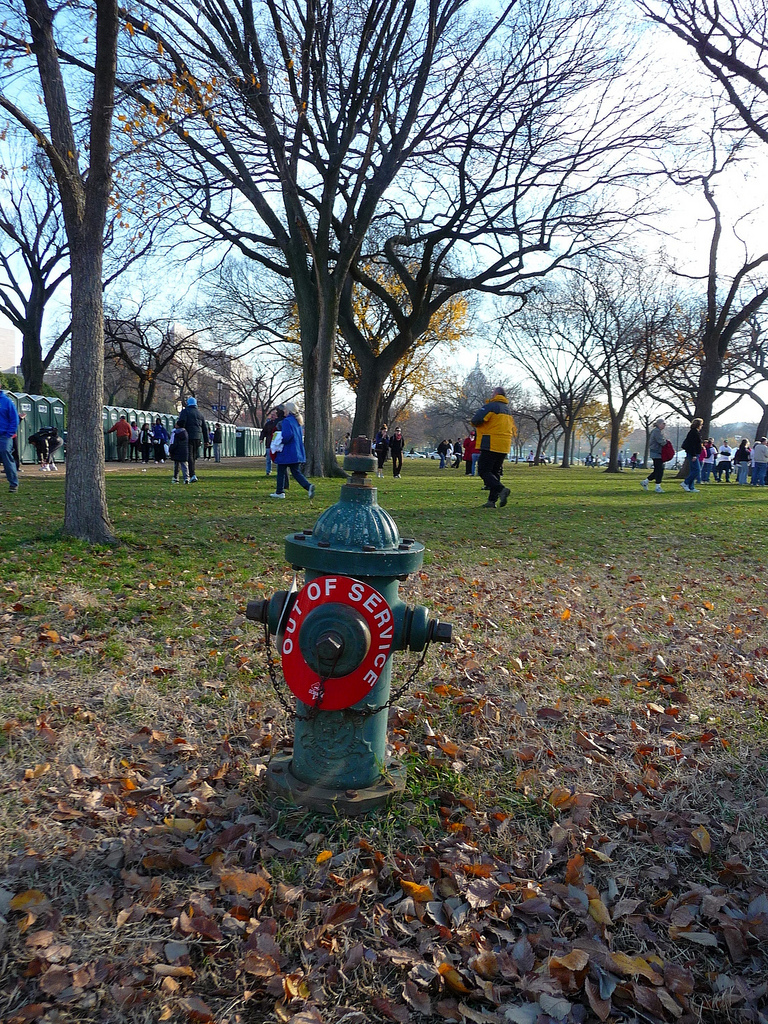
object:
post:
[292, 575, 400, 791]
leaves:
[545, 941, 595, 982]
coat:
[273, 415, 308, 465]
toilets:
[107, 404, 121, 460]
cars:
[406, 451, 427, 458]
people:
[0, 384, 23, 509]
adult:
[178, 395, 212, 484]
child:
[168, 417, 195, 488]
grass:
[378, 463, 768, 564]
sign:
[280, 576, 393, 711]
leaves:
[35, 947, 97, 1006]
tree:
[339, 229, 467, 472]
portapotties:
[17, 397, 37, 464]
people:
[526, 448, 536, 468]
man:
[467, 381, 521, 514]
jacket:
[468, 392, 518, 456]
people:
[107, 408, 137, 467]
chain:
[261, 623, 459, 728]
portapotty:
[48, 397, 67, 462]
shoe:
[496, 483, 513, 507]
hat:
[186, 395, 201, 409]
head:
[186, 395, 198, 409]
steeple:
[469, 347, 487, 367]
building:
[105, 318, 141, 407]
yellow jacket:
[462, 389, 516, 457]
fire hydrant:
[244, 464, 452, 803]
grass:
[0, 463, 349, 591]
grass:
[245, 755, 464, 886]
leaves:
[459, 867, 499, 907]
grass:
[427, 484, 600, 574]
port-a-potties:
[109, 404, 123, 465]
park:
[0, 389, 768, 1024]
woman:
[266, 402, 318, 501]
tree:
[34, 0, 144, 548]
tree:
[208, 0, 348, 487]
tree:
[520, 336, 599, 470]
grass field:
[0, 458, 768, 866]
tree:
[582, 384, 612, 461]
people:
[585, 449, 597, 471]